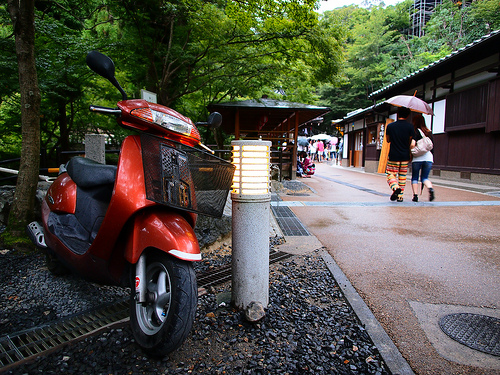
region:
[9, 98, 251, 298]
the motorcycle is red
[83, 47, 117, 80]
a black side view mirror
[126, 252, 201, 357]
a black tire on the scooter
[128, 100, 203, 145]
a headlight on the scooter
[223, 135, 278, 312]
a gray post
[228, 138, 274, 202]
a light on the post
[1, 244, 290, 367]
a vent on the ground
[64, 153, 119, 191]
a black seat on the scooter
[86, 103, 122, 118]
a handlebar on the scooter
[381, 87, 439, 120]
a brown umbrella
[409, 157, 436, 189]
a pair of blue pants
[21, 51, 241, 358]
parked red motorized scooter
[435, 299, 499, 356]
manhole cover on street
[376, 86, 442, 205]
man and woman under umbrella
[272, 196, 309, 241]
metal sewer grate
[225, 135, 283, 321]
small lit light post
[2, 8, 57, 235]
tree trunk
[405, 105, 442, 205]
woman wearing blue jeans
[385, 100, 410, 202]
man wearing long striped pants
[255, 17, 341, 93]
many green leaves on branches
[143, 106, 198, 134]
unlit scooter headlight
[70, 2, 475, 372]
walkway through tree-filled park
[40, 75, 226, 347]
red motorbike parked under trees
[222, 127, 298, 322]
glowing lamp on top of a grey cylinder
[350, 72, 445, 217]
two people sharing an umbrella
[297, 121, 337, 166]
a group of people farther down the path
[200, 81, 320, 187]
open structure with dark roof and wooden supports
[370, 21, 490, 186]
dark and flat building with windows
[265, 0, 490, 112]
trees growing over buildings and walkway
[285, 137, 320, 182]
woman kneeling in front of building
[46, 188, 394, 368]
gravel and gratings next to walkway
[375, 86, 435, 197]
a couple with an open umbrella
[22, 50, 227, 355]
a parked orange motorscooter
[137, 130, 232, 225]
a black metal basket is on the scooter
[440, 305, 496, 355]
a black manhole cover is in the street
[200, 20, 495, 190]
buildings on the side of the street are wooden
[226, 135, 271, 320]
a light post is streetside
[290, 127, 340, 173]
people are under umbrellas at the end of the street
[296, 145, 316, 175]
a person kneeling before the building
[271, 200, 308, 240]
grates are next to the street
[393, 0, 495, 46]
a building is up in the trees